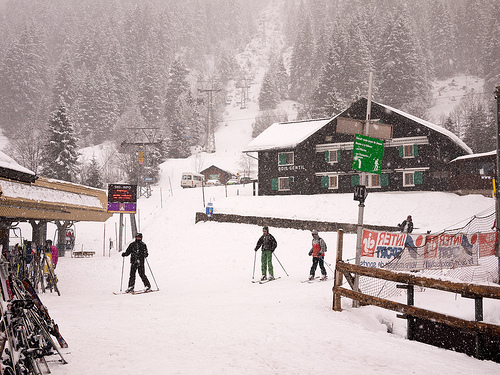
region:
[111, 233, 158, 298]
a skier going down hill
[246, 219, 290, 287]
a skier going down hill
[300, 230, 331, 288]
a skier going down hill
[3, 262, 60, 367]
a stack of skis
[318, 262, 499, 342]
a brown wood fence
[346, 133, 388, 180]
a green directional sign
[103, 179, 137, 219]
a directional sign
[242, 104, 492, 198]
a large building in distance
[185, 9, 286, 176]
a snowy ski slope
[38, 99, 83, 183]
a snowy green tree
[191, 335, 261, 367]
the snow is white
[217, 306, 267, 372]
the snow is white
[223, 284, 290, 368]
the snow is white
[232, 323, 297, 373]
the snow is white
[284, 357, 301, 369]
the snow is white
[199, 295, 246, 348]
the snow is white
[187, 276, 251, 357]
the snow is white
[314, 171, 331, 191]
the shutters are green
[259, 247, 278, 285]
the pants are green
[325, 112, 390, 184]
the sign is green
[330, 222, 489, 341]
the fence is small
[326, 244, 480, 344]
the fence is wooden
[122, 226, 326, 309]
the people are on skis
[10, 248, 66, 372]
the skis are leaning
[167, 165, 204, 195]
the van is white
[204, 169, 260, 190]
the cars are parked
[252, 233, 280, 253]
the jacket is black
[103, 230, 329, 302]
three people on skis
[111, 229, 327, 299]
three people skiing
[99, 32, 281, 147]
the snow is falling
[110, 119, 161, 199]
the ski lift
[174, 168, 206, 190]
the van beside the ski lift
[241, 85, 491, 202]
the brown ski lodge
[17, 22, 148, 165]
the pine trees on the mountain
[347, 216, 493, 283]
the black net on the fence post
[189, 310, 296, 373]
the snow is white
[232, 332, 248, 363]
the snow is white